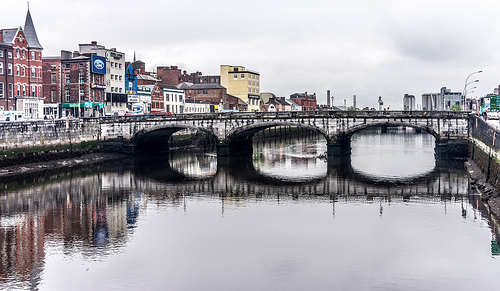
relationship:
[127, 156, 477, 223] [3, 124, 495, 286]
reflection in water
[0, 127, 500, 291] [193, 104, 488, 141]
river next to bridge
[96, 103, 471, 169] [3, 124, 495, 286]
bridge above water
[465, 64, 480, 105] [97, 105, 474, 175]
light next to bridge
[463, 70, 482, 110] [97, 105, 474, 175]
light next to bridge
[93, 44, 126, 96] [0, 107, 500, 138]
white building next to bridge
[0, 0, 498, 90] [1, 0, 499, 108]
clouds in sky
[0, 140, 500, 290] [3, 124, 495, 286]
reflection in water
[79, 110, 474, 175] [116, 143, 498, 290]
bridge over water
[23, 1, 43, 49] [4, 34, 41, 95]
roof on building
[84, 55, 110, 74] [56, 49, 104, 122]
sign on building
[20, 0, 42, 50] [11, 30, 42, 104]
roof atop building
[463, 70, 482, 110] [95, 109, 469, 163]
light to right of bridge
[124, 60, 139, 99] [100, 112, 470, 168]
blue building to left of bridge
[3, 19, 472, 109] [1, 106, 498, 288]
buildings surrounding water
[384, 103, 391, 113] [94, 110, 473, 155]
people crossing bridge